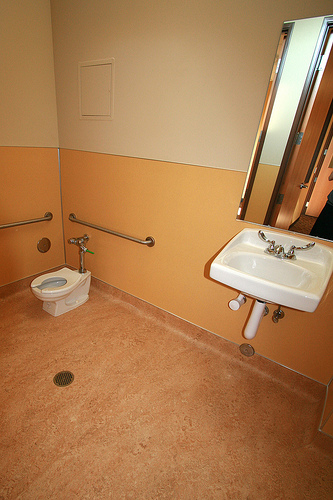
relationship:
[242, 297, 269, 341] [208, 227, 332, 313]
pipe under sink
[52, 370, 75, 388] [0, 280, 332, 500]
drain in floor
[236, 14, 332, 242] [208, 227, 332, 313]
mirror over sink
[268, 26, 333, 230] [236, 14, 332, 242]
door reflected in mirror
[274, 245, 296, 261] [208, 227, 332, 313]
faucet on sink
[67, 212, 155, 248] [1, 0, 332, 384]
railing on wall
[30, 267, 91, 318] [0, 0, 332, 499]
toilet in bathroom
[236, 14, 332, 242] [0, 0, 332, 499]
mirror in bathroom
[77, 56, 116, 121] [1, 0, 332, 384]
panel on wall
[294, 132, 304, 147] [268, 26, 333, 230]
hinge on door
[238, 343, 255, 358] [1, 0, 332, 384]
orb on wall